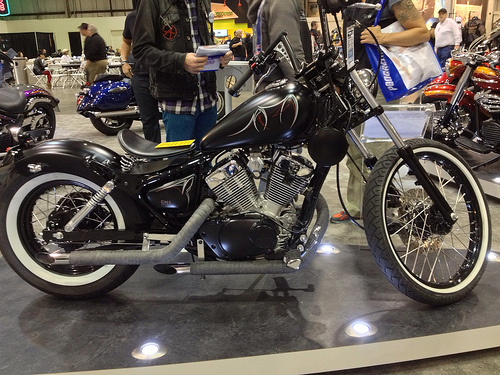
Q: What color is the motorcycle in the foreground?
A: Black.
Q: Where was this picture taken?
A: Motorcycle show.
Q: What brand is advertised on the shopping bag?
A: Progressive.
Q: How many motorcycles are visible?
A: Four.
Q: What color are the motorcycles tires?
A: Black and white.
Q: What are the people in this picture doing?
A: Looking at motorcycles.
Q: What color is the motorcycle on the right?
A: Red.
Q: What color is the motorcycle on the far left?
A: Purple.